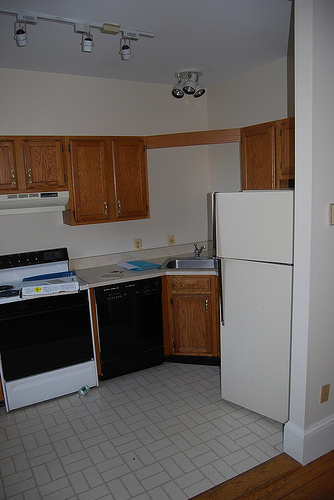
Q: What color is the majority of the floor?
A: White.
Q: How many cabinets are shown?
A: Seven.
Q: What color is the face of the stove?
A: Black.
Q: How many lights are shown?
A: Six.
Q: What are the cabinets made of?
A: Wood.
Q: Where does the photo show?
A: Kitchen.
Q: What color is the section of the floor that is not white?
A: Brown.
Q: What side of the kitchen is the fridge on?
A: Right.